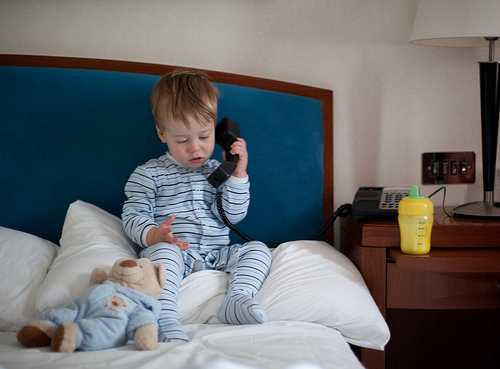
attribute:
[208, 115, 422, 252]
telephone — black, corded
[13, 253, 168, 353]
teddy bear — tan, brown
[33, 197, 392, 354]
pillow — white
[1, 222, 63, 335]
pillow — white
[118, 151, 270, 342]
outfit — white, striped, blue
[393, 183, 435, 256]
cup — yellow, plastic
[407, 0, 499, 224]
lamp — tall, silver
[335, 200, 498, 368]
table — wooden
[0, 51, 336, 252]
headboard — blue, wood, brown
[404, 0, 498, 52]
shade — white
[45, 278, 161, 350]
pajamas — blue, striped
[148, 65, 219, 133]
hair — brown